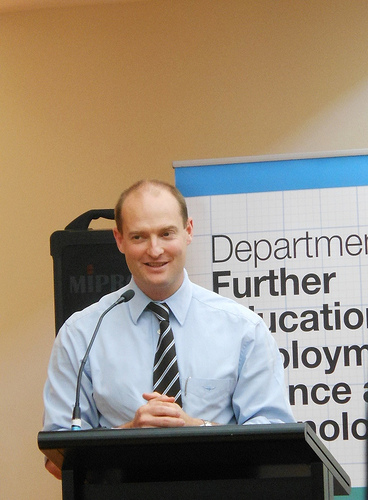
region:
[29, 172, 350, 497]
man standing before podium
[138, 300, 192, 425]
striped black and blue tie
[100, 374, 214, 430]
folded hand of man at podium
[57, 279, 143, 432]
black microphone attached to black podium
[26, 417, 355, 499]
tall black podium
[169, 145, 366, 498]
blue and white screen behind man at podium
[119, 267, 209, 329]
blue collar of blue shirt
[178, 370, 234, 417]
blue pocket on front of blue shirt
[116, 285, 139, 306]
foam tip of microphone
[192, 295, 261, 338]
seam in blue collared shirt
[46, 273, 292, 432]
the man is wearing a long sleeve shirt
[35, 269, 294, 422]
the shirt is blue in color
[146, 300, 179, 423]
the man is wearing a tie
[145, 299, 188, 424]
the tie has stripes across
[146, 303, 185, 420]
the tie is black in color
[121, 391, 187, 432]
the man is crossing his hands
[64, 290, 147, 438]
a microphone is on the podium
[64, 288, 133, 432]
the mic is black in color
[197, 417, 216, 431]
the man is wearing a watch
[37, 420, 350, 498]
the podium is black in color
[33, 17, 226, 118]
a wall with beige paint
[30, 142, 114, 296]
an amplifier for a microphone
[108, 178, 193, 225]
a mans balding head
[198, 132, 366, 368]
the sign for a seminar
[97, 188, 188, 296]
a grown man smiling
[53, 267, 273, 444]
a blue button down shirt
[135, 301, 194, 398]
a black and blue striped tie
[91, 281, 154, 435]
a podiums black microphone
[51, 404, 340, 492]
a large black podium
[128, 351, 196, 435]
a man clasping his hands together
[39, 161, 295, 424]
man wearing blue dress shirt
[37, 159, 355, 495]
man standing at podium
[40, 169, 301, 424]
man with brown and blue tie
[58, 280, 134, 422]
black microphone in front of man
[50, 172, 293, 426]
man with hands clasped in front of him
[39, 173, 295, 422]
man is smiling and looking to the right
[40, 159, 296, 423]
man wearing dress shirt and tie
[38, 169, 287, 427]
man wearing button up shirt and tie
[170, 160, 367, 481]
blue and white sign behind man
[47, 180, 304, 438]
man resting hands on podium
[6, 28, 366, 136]
a white wall behind the man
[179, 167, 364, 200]
the blue top of the sign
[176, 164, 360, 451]
a sign behind the man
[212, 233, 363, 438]
writing on the sign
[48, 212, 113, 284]
a black speaker behind the man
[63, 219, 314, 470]
a man talking into a microphone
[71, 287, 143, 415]
a black microphone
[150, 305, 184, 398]
a black and white tie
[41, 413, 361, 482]
a black podium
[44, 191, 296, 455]
a man wearing a blue shirt